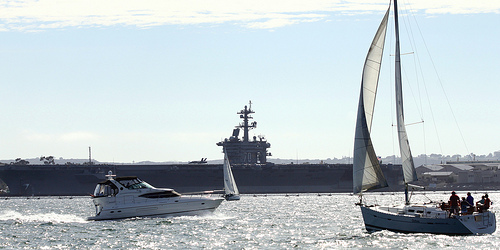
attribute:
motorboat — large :
[91, 148, 236, 241]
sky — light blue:
[0, 0, 495, 163]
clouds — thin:
[0, 1, 500, 34]